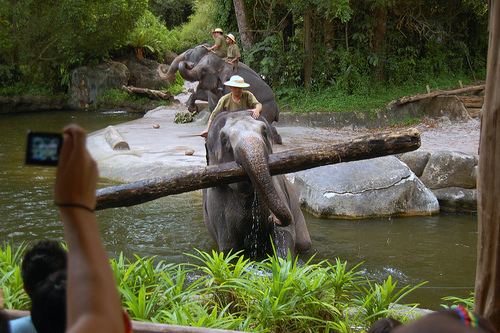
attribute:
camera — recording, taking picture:
[23, 129, 67, 165]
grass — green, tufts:
[287, 67, 377, 115]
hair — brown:
[22, 236, 67, 331]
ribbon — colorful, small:
[452, 303, 481, 329]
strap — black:
[56, 201, 94, 211]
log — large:
[91, 123, 427, 207]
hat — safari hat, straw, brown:
[219, 74, 253, 91]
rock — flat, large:
[87, 91, 484, 216]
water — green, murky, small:
[1, 107, 488, 306]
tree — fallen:
[387, 73, 488, 104]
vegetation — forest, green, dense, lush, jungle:
[1, 2, 482, 112]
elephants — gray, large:
[155, 39, 322, 261]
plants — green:
[2, 240, 402, 331]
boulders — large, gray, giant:
[66, 51, 175, 109]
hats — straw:
[213, 27, 238, 42]